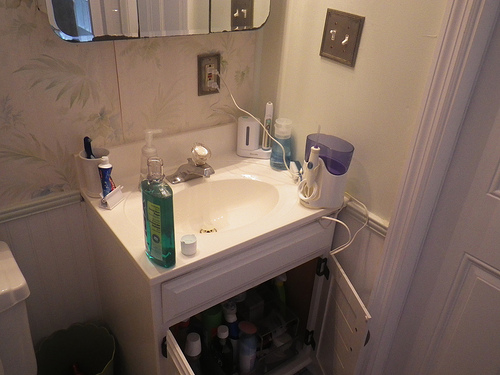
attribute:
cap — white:
[179, 230, 196, 258]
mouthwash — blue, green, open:
[139, 178, 181, 265]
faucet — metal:
[167, 144, 225, 186]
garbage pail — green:
[37, 321, 125, 374]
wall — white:
[262, 2, 457, 226]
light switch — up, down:
[318, 8, 364, 67]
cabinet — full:
[167, 242, 335, 374]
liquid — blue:
[271, 146, 292, 166]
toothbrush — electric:
[296, 118, 324, 205]